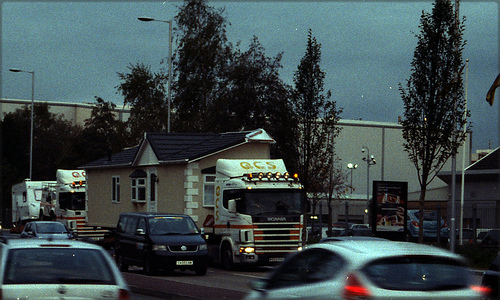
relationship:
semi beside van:
[207, 158, 308, 273] [112, 212, 208, 279]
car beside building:
[398, 207, 451, 242] [433, 140, 498, 248]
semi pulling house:
[207, 158, 308, 273] [80, 129, 276, 236]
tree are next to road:
[398, 0, 474, 237] [0, 228, 499, 298]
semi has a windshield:
[207, 158, 308, 273] [246, 190, 302, 216]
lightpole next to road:
[137, 17, 174, 134] [0, 228, 499, 298]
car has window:
[242, 239, 487, 299] [364, 256, 466, 289]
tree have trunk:
[398, 0, 474, 237] [419, 158, 427, 244]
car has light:
[242, 239, 487, 299] [342, 274, 493, 296]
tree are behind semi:
[398, 0, 474, 237] [207, 158, 308, 273]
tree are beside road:
[398, 0, 474, 237] [0, 228, 499, 298]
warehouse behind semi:
[0, 98, 470, 231] [207, 158, 308, 273]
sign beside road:
[373, 179, 408, 236] [0, 228, 499, 298]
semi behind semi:
[53, 169, 109, 242] [207, 158, 308, 273]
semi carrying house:
[207, 158, 308, 273] [80, 129, 276, 236]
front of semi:
[241, 180, 301, 261] [207, 158, 308, 273]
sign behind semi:
[373, 179, 408, 236] [207, 158, 308, 273]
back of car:
[348, 249, 483, 299] [242, 239, 487, 299]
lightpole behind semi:
[137, 17, 174, 134] [207, 158, 308, 273]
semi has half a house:
[207, 158, 308, 273] [80, 129, 276, 236]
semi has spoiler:
[207, 158, 308, 273] [213, 159, 289, 181]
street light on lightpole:
[136, 17, 170, 30] [137, 17, 174, 134]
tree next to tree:
[398, 6, 473, 237] [291, 21, 357, 211]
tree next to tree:
[291, 21, 357, 211] [398, 6, 473, 237]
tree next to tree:
[291, 21, 357, 211] [211, 35, 297, 170]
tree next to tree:
[211, 35, 297, 170] [291, 21, 357, 211]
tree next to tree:
[211, 35, 297, 170] [162, 3, 234, 151]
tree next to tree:
[162, 3, 234, 151] [211, 35, 297, 170]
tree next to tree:
[162, 3, 234, 151] [116, 61, 169, 154]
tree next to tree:
[116, 61, 169, 154] [78, 91, 134, 151]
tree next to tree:
[116, 61, 169, 154] [162, 3, 234, 151]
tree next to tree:
[78, 91, 134, 151] [116, 61, 169, 154]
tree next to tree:
[78, 91, 134, 151] [1, 99, 87, 192]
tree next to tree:
[1, 99, 87, 192] [78, 91, 134, 151]